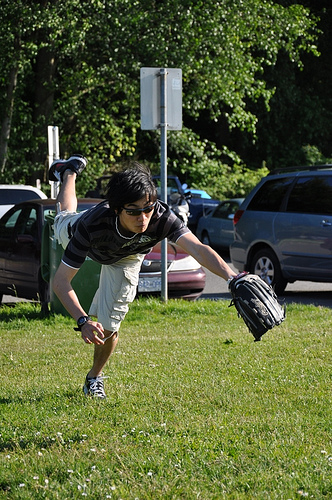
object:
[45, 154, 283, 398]
man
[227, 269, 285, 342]
catcher's mitt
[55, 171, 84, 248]
leg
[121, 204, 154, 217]
sunglasses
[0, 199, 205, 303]
car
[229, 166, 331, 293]
minivan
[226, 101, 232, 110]
leaves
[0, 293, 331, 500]
grass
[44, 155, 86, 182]
shoe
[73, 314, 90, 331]
watch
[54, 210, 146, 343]
shorts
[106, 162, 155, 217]
hair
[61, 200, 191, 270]
shirt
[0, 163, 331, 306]
parking lot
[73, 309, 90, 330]
wrist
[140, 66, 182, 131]
sign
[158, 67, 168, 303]
pole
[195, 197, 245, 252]
car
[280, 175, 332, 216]
window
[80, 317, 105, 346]
hand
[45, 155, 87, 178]
foot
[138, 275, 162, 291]
license plate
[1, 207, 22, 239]
window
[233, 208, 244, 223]
tail light